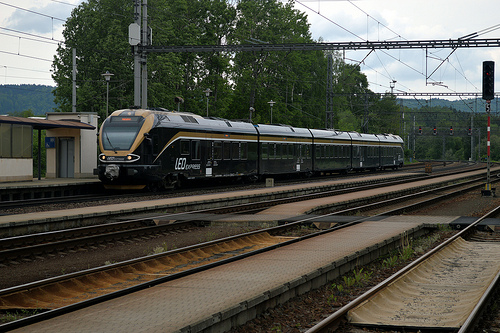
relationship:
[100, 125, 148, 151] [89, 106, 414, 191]
windshield of train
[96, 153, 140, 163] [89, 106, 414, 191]
headlights on train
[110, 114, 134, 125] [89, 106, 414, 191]
sign on train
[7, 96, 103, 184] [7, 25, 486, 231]
building at train station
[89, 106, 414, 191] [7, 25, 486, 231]
train at train station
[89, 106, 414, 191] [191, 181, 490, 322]
train on tracks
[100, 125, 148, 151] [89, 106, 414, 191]
windshield on train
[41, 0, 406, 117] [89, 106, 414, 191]
trees behind train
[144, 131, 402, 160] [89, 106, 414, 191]
stripe on train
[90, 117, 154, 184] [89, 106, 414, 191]
front of train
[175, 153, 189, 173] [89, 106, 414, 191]
word on train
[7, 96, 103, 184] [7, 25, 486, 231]
buildings at train station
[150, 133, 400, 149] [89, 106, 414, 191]
stripes on train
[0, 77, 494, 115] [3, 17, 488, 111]
mountians in back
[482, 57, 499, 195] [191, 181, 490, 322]
pole on tracks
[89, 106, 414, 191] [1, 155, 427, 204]
train on track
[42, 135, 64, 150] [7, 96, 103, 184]
sign on building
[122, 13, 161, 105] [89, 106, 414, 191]
poles beside train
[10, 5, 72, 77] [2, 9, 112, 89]
lines in air